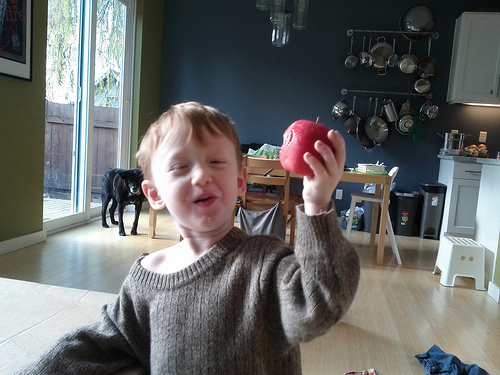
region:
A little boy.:
[81, 93, 412, 371]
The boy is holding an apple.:
[266, 95, 358, 211]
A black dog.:
[81, 140, 142, 240]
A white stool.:
[421, 221, 487, 296]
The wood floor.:
[393, 302, 479, 337]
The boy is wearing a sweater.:
[8, 197, 378, 372]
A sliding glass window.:
[45, 1, 140, 226]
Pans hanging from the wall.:
[332, 6, 438, 147]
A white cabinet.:
[447, 7, 497, 97]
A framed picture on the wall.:
[0, 2, 39, 84]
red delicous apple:
[256, 95, 361, 177]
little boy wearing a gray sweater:
[102, 120, 347, 337]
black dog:
[91, 156, 176, 231]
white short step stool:
[428, 223, 494, 297]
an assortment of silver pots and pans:
[331, 31, 461, 169]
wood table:
[214, 110, 416, 250]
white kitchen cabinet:
[440, 8, 493, 108]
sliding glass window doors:
[44, 0, 161, 200]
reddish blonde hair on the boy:
[115, 93, 228, 158]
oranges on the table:
[457, 128, 492, 170]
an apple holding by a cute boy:
[273, 115, 351, 184]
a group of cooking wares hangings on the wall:
[346, 28, 443, 78]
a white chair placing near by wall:
[434, 235, 491, 291]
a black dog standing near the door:
[101, 162, 147, 233]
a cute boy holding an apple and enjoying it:
[118, 115, 356, 370]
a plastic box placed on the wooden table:
[358, 157, 392, 175]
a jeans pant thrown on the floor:
[413, 341, 499, 373]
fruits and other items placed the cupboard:
[445, 129, 499, 161]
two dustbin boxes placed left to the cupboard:
[398, 170, 450, 240]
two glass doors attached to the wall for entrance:
[41, 5, 121, 214]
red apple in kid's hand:
[274, 115, 334, 183]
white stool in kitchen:
[419, 232, 486, 295]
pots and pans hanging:
[332, 23, 433, 153]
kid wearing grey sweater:
[124, 253, 364, 345]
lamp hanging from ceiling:
[249, 1, 311, 60]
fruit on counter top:
[466, 143, 488, 157]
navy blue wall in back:
[238, 99, 281, 131]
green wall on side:
[3, 182, 45, 229]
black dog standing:
[98, 171, 133, 241]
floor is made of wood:
[363, 279, 408, 341]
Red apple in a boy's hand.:
[276, 105, 360, 194]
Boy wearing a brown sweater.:
[34, 94, 374, 374]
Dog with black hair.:
[96, 161, 148, 241]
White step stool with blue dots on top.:
[426, 226, 495, 295]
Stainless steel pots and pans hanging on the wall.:
[334, 23, 446, 155]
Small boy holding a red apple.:
[57, 99, 345, 374]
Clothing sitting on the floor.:
[406, 332, 492, 373]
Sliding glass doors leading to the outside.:
[35, 0, 150, 239]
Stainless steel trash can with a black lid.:
[420, 173, 448, 246]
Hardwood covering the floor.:
[369, 263, 443, 347]